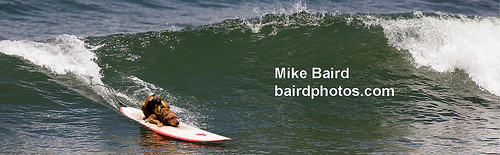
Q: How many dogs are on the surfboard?
A: One.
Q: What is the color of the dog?
A: Brown.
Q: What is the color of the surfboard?
A: White and red.